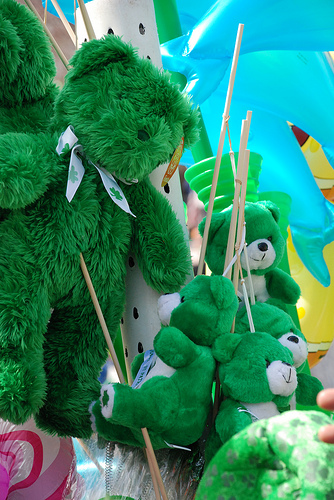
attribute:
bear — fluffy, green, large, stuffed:
[22, 73, 144, 374]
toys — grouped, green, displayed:
[44, 74, 316, 462]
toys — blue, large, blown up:
[164, 16, 328, 143]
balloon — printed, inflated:
[8, 411, 73, 481]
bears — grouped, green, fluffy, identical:
[159, 194, 323, 444]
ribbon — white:
[40, 135, 146, 234]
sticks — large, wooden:
[204, 89, 266, 281]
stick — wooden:
[81, 259, 169, 473]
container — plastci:
[33, 5, 134, 51]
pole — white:
[115, 12, 206, 339]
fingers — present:
[294, 379, 331, 444]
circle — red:
[4, 428, 56, 494]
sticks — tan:
[182, 63, 283, 324]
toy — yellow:
[273, 243, 325, 313]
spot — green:
[220, 453, 277, 500]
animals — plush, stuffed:
[94, 113, 276, 378]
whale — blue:
[184, 16, 325, 81]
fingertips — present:
[291, 356, 332, 435]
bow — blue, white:
[28, 143, 127, 211]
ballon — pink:
[1, 421, 94, 487]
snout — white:
[235, 241, 282, 271]